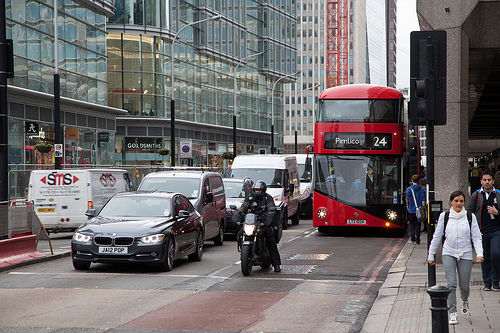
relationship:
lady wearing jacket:
[426, 190, 485, 324] [428, 205, 485, 255]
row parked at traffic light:
[72, 147, 319, 274] [407, 29, 449, 129]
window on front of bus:
[312, 154, 402, 203] [311, 81, 421, 240]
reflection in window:
[315, 155, 374, 201] [318, 95, 405, 127]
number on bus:
[370, 132, 389, 149] [311, 81, 421, 240]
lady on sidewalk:
[426, 190, 483, 323] [359, 230, 497, 332]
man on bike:
[467, 173, 500, 290] [216, 190, 304, 284]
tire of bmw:
[187, 227, 204, 263] [69, 188, 207, 273]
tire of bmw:
[159, 237, 175, 272] [69, 188, 207, 273]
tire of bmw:
[73, 257, 90, 271] [69, 188, 207, 273]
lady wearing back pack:
[426, 190, 485, 324] [427, 208, 449, 240]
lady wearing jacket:
[426, 190, 485, 324] [427, 207, 486, 260]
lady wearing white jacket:
[426, 190, 485, 324] [427, 211, 444, 260]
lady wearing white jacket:
[426, 190, 485, 324] [470, 212, 482, 255]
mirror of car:
[174, 205, 188, 219] [37, 157, 215, 273]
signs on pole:
[160, 289, 246, 314] [50, 69, 62, 171]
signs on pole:
[50, 143, 67, 160] [52, 73, 62, 172]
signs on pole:
[177, 134, 195, 162] [167, 96, 179, 163]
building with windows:
[0, 3, 288, 238] [57, 40, 116, 77]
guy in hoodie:
[403, 170, 428, 248] [405, 182, 426, 211]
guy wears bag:
[403, 170, 428, 248] [409, 186, 426, 221]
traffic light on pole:
[412, 27, 447, 122] [427, 130, 444, 292]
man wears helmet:
[467, 173, 500, 290] [249, 177, 266, 190]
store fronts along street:
[8, 101, 267, 173] [3, 263, 364, 332]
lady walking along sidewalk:
[426, 190, 485, 324] [379, 215, 496, 329]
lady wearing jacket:
[426, 190, 485, 324] [419, 212, 489, 271]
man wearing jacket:
[469, 173, 499, 288] [427, 207, 486, 260]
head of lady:
[249, 178, 269, 200] [426, 190, 483, 323]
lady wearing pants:
[426, 190, 483, 323] [434, 245, 474, 320]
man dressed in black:
[231, 182, 313, 270] [242, 187, 282, 266]